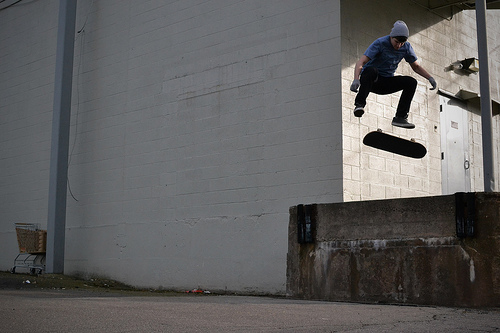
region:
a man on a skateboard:
[267, 28, 494, 219]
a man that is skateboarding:
[332, 26, 492, 237]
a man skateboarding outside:
[317, 3, 499, 193]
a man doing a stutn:
[340, 16, 489, 223]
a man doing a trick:
[310, 1, 460, 208]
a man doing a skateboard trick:
[277, 5, 496, 229]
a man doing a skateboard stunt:
[335, 26, 490, 253]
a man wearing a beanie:
[299, 1, 494, 182]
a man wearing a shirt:
[321, 19, 471, 140]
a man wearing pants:
[329, 21, 470, 153]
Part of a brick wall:
[220, 228, 273, 279]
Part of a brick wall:
[257, 162, 314, 190]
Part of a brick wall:
[275, 126, 340, 161]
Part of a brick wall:
[275, 74, 341, 139]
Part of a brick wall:
[207, 128, 257, 174]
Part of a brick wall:
[122, 165, 182, 215]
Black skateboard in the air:
[356, 115, 444, 192]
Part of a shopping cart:
[3, 205, 59, 285]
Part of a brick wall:
[78, 83, 130, 144]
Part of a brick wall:
[124, 14, 183, 82]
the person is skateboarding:
[341, 17, 436, 162]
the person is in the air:
[333, 19, 439, 131]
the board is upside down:
[358, 124, 428, 161]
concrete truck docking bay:
[288, 188, 498, 311]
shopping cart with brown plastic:
[8, 217, 53, 282]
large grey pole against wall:
[43, 0, 75, 282]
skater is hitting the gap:
[331, 18, 438, 163]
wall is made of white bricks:
[1, 3, 498, 295]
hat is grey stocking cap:
[387, 17, 412, 39]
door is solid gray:
[436, 87, 474, 198]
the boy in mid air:
[350, 19, 438, 129]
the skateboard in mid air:
[363, 127, 427, 159]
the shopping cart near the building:
[10, 221, 47, 276]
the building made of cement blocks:
[0, 1, 498, 303]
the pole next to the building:
[43, 0, 75, 275]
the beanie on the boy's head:
[387, 19, 409, 39]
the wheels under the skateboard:
[375, 126, 415, 142]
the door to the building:
[439, 90, 471, 193]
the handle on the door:
[463, 157, 470, 170]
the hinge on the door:
[437, 105, 443, 112]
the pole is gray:
[44, 23, 80, 270]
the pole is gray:
[34, 18, 114, 288]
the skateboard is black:
[372, 123, 449, 182]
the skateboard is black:
[341, 103, 441, 183]